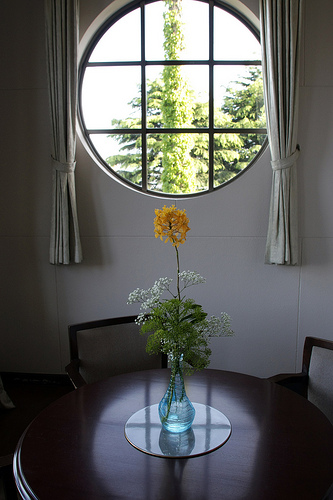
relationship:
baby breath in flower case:
[135, 311, 150, 328] [157, 352, 196, 434]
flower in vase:
[152, 205, 191, 424] [157, 353, 196, 431]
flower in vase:
[173, 270, 205, 301] [157, 353, 196, 431]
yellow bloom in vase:
[152, 203, 192, 248] [157, 353, 196, 431]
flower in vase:
[199, 309, 235, 338] [157, 353, 196, 431]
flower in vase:
[125, 283, 151, 306] [157, 353, 196, 431]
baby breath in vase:
[125, 268, 235, 372] [159, 358, 195, 434]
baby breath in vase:
[125, 268, 235, 372] [157, 353, 196, 431]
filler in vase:
[146, 300, 206, 362] [157, 353, 196, 431]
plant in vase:
[144, 305, 204, 356] [157, 353, 196, 431]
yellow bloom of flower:
[152, 205, 191, 246] [126, 205, 231, 435]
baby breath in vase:
[125, 268, 235, 372] [131, 374, 212, 441]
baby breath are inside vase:
[125, 268, 235, 372] [144, 373, 204, 431]